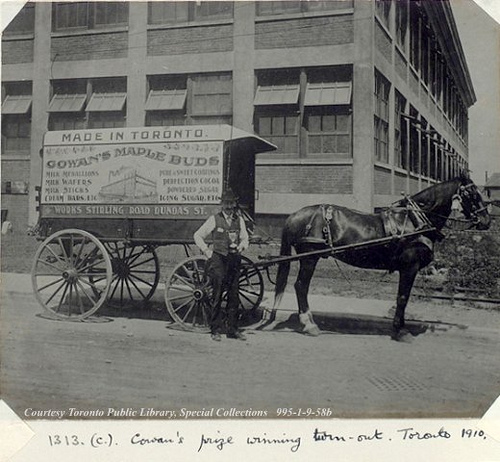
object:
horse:
[273, 167, 492, 343]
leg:
[391, 267, 415, 344]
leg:
[293, 246, 318, 336]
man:
[193, 187, 250, 341]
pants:
[205, 252, 240, 331]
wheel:
[31, 228, 113, 321]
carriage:
[29, 123, 278, 334]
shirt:
[193, 210, 250, 258]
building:
[0, 0, 479, 232]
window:
[254, 109, 297, 154]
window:
[145, 90, 186, 114]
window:
[90, 78, 126, 121]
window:
[303, 110, 352, 158]